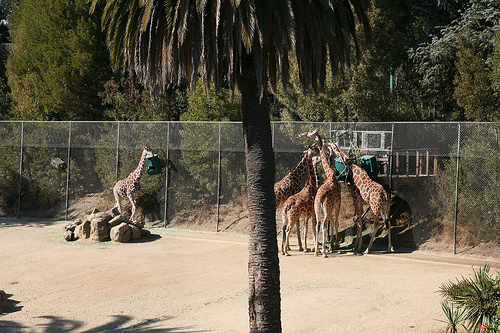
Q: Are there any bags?
A: No, there are no bags.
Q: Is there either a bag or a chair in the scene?
A: No, there are no bags or chairs.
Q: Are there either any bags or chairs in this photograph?
A: No, there are no bags or chairs.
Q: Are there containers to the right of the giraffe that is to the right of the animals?
A: Yes, there is a container to the right of the giraffe.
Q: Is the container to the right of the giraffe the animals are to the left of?
A: Yes, the container is to the right of the giraffe.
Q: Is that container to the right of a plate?
A: No, the container is to the right of the giraffe.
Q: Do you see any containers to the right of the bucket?
A: No, the container is to the left of the bucket.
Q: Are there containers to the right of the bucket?
A: No, the container is to the left of the bucket.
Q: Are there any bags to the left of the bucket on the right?
A: No, there is a container to the left of the bucket.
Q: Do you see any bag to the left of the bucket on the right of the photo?
A: No, there is a container to the left of the bucket.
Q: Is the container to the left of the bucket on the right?
A: Yes, the container is to the left of the bucket.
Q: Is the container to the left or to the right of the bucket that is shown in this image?
A: The container is to the left of the bucket.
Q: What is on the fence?
A: The container is on the fence.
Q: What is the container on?
A: The container is on the fence.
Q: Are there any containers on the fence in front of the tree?
A: Yes, there is a container on the fence.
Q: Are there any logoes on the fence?
A: No, there is a container on the fence.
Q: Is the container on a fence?
A: Yes, the container is on a fence.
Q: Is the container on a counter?
A: No, the container is on a fence.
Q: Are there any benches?
A: No, there are no benches.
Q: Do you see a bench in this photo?
A: No, there are no benches.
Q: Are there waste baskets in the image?
A: No, there are no waste baskets.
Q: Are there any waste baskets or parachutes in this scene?
A: No, there are no waste baskets or parachutes.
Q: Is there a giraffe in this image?
A: Yes, there are giraffes.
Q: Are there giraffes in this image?
A: Yes, there are giraffes.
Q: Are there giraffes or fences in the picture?
A: Yes, there are giraffes.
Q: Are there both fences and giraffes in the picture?
A: Yes, there are both giraffes and a fence.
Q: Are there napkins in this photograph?
A: No, there are no napkins.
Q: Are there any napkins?
A: No, there are no napkins.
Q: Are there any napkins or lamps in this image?
A: No, there are no napkins or lamps.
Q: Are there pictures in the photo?
A: No, there are no pictures.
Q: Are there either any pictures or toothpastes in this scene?
A: No, there are no pictures or toothpastes.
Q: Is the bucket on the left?
A: No, the bucket is on the right of the image.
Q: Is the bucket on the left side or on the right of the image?
A: The bucket is on the right of the image.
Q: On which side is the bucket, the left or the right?
A: The bucket is on the right of the image.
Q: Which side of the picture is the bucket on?
A: The bucket is on the right of the image.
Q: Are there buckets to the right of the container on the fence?
A: Yes, there is a bucket to the right of the container.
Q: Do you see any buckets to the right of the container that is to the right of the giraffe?
A: Yes, there is a bucket to the right of the container.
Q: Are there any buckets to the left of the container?
A: No, the bucket is to the right of the container.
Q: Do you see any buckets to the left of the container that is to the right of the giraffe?
A: No, the bucket is to the right of the container.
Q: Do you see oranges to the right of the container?
A: No, there is a bucket to the right of the container.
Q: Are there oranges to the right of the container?
A: No, there is a bucket to the right of the container.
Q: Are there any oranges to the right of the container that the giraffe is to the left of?
A: No, there is a bucket to the right of the container.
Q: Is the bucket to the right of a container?
A: Yes, the bucket is to the right of a container.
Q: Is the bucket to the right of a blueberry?
A: No, the bucket is to the right of a container.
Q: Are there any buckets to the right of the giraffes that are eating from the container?
A: Yes, there is a bucket to the right of the giraffes.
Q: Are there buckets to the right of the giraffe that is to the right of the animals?
A: Yes, there is a bucket to the right of the giraffe.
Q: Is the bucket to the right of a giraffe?
A: Yes, the bucket is to the right of a giraffe.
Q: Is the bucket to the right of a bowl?
A: No, the bucket is to the right of a giraffe.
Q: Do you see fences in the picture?
A: Yes, there is a fence.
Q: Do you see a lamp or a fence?
A: Yes, there is a fence.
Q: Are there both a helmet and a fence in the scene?
A: No, there is a fence but no helmets.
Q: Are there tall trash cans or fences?
A: Yes, there is a tall fence.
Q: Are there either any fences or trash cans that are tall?
A: Yes, the fence is tall.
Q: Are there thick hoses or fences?
A: Yes, there is a thick fence.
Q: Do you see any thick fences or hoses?
A: Yes, there is a thick fence.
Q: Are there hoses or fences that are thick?
A: Yes, the fence is thick.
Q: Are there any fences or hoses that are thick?
A: Yes, the fence is thick.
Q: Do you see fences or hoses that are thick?
A: Yes, the fence is thick.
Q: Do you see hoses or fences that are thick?
A: Yes, the fence is thick.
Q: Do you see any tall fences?
A: Yes, there is a tall fence.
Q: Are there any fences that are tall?
A: Yes, there is a fence that is tall.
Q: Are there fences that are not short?
A: Yes, there is a tall fence.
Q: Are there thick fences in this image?
A: Yes, there is a thick fence.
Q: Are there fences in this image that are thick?
A: Yes, there is a fence that is thick.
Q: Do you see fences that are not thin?
A: Yes, there is a thick fence.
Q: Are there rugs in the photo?
A: No, there are no rugs.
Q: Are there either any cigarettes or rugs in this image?
A: No, there are no rugs or cigarettes.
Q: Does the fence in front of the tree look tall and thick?
A: Yes, the fence is tall and thick.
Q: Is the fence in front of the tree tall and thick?
A: Yes, the fence is tall and thick.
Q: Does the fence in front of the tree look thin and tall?
A: No, the fence is tall but thick.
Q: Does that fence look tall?
A: Yes, the fence is tall.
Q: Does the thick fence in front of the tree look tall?
A: Yes, the fence is tall.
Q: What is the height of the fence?
A: The fence is tall.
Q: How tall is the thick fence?
A: The fence is tall.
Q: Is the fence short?
A: No, the fence is tall.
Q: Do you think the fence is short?
A: No, the fence is tall.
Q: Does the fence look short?
A: No, the fence is tall.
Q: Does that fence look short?
A: No, the fence is tall.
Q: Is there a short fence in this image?
A: No, there is a fence but it is tall.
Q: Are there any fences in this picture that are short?
A: No, there is a fence but it is tall.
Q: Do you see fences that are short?
A: No, there is a fence but it is tall.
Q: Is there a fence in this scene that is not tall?
A: No, there is a fence but it is tall.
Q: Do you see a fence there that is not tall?
A: No, there is a fence but it is tall.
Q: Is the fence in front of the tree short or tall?
A: The fence is tall.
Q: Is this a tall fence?
A: Yes, this is a tall fence.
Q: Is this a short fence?
A: No, this is a tall fence.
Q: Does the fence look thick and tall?
A: Yes, the fence is thick and tall.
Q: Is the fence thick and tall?
A: Yes, the fence is thick and tall.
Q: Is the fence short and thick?
A: No, the fence is thick but tall.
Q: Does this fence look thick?
A: Yes, the fence is thick.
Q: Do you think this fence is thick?
A: Yes, the fence is thick.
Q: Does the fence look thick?
A: Yes, the fence is thick.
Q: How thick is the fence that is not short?
A: The fence is thick.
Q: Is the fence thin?
A: No, the fence is thick.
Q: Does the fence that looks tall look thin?
A: No, the fence is thick.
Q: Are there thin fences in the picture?
A: No, there is a fence but it is thick.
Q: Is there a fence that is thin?
A: No, there is a fence but it is thick.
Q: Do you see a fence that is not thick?
A: No, there is a fence but it is thick.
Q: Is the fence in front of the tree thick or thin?
A: The fence is thick.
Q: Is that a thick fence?
A: Yes, that is a thick fence.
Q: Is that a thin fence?
A: No, that is a thick fence.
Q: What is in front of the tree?
A: The fence is in front of the tree.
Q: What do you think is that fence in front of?
A: The fence is in front of the tree.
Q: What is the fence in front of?
A: The fence is in front of the tree.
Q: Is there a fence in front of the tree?
A: Yes, there is a fence in front of the tree.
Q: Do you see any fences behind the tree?
A: No, the fence is in front of the tree.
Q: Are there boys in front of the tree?
A: No, there is a fence in front of the tree.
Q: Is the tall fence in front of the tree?
A: Yes, the fence is in front of the tree.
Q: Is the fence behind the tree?
A: No, the fence is in front of the tree.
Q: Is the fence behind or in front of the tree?
A: The fence is in front of the tree.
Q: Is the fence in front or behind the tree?
A: The fence is in front of the tree.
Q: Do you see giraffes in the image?
A: Yes, there are giraffes.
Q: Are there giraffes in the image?
A: Yes, there are giraffes.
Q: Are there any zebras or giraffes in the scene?
A: Yes, there are giraffes.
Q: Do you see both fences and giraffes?
A: Yes, there are both giraffes and a fence.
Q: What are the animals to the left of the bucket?
A: The animals are giraffes.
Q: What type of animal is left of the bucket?
A: The animals are giraffes.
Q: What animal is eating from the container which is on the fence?
A: The giraffes are eating from the container.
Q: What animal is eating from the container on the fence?
A: The giraffes are eating from the container.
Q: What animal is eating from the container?
A: The giraffes are eating from the container.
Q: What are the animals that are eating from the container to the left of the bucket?
A: The animals are giraffes.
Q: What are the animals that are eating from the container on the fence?
A: The animals are giraffes.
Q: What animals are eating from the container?
A: The animals are giraffes.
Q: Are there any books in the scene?
A: No, there are no books.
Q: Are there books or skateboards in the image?
A: No, there are no books or skateboards.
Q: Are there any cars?
A: No, there are no cars.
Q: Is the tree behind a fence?
A: Yes, the tree is behind a fence.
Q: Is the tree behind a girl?
A: No, the tree is behind a fence.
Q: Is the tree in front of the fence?
A: No, the tree is behind the fence.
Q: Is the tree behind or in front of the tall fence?
A: The tree is behind the fence.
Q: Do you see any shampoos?
A: No, there are no shampoos.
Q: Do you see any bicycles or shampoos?
A: No, there are no shampoos or bicycles.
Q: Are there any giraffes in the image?
A: Yes, there is a giraffe.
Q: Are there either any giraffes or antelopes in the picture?
A: Yes, there is a giraffe.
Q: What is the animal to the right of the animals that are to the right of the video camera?
A: The animal is a giraffe.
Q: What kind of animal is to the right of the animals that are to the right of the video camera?
A: The animal is a giraffe.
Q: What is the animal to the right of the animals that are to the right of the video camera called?
A: The animal is a giraffe.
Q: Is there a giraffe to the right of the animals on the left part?
A: Yes, there is a giraffe to the right of the animals.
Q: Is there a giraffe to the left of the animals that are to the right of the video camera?
A: No, the giraffe is to the right of the animals.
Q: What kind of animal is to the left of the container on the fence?
A: The animal is a giraffe.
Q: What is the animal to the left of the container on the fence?
A: The animal is a giraffe.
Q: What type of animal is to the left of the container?
A: The animal is a giraffe.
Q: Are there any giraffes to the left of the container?
A: Yes, there is a giraffe to the left of the container.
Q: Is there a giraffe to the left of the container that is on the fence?
A: Yes, there is a giraffe to the left of the container.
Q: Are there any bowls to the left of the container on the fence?
A: No, there is a giraffe to the left of the container.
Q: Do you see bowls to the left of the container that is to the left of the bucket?
A: No, there is a giraffe to the left of the container.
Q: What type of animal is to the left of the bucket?
A: The animal is a giraffe.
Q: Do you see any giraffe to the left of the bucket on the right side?
A: Yes, there is a giraffe to the left of the bucket.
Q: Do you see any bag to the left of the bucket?
A: No, there is a giraffe to the left of the bucket.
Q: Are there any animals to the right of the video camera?
A: Yes, there are animals to the right of the video camera.